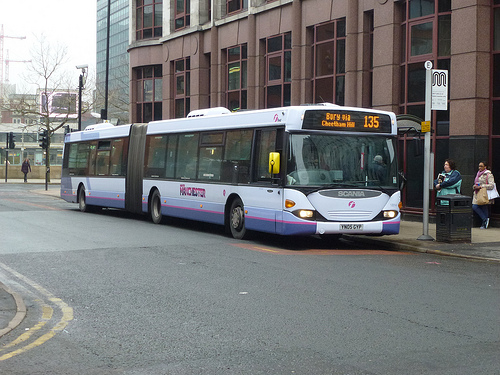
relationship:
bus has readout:
[57, 100, 402, 246] [318, 108, 384, 130]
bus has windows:
[57, 100, 402, 246] [62, 134, 129, 174]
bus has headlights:
[57, 100, 402, 246] [296, 208, 395, 221]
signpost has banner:
[421, 57, 452, 242] [431, 69, 450, 113]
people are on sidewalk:
[436, 159, 500, 227] [402, 217, 499, 264]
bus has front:
[57, 100, 402, 246] [283, 103, 404, 246]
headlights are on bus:
[296, 208, 395, 221] [57, 100, 402, 246]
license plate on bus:
[335, 220, 365, 234] [57, 100, 402, 246]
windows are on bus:
[62, 134, 129, 174] [57, 100, 402, 246]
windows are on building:
[133, 7, 448, 130] [132, 1, 497, 221]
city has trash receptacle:
[2, 2, 498, 372] [433, 191, 475, 245]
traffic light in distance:
[4, 131, 16, 183] [2, 122, 68, 189]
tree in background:
[17, 45, 67, 195] [0, 1, 132, 204]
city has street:
[2, 2, 498, 372] [1, 181, 500, 373]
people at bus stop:
[436, 159, 500, 227] [416, 55, 496, 252]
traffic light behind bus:
[4, 131, 16, 183] [57, 100, 402, 246]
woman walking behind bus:
[19, 157, 32, 183] [57, 100, 402, 246]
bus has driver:
[57, 100, 402, 246] [295, 144, 330, 188]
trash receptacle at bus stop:
[433, 191, 475, 245] [416, 55, 496, 252]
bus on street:
[57, 100, 402, 246] [1, 181, 500, 373]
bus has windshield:
[57, 100, 402, 246] [284, 131, 400, 189]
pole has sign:
[422, 59, 435, 243] [431, 69, 450, 113]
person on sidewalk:
[432, 159, 463, 195] [402, 217, 499, 264]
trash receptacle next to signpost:
[433, 191, 475, 245] [421, 57, 452, 242]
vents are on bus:
[181, 103, 234, 119] [57, 100, 402, 246]